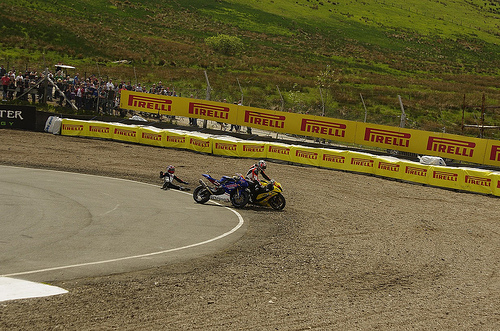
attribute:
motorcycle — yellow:
[232, 177, 287, 213]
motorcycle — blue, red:
[192, 172, 234, 203]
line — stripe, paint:
[1, 162, 243, 279]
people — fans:
[2, 66, 176, 120]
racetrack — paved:
[0, 160, 249, 286]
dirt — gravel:
[0, 129, 499, 327]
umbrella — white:
[53, 63, 75, 70]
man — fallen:
[157, 164, 193, 193]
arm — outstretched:
[175, 173, 190, 184]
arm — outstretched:
[157, 169, 166, 179]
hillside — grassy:
[1, 2, 500, 71]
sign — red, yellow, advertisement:
[62, 117, 88, 139]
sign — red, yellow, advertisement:
[83, 119, 112, 139]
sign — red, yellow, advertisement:
[111, 123, 139, 144]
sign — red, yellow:
[136, 127, 165, 146]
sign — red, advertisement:
[164, 129, 188, 150]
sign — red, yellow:
[186, 131, 213, 156]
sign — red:
[211, 137, 236, 158]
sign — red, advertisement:
[263, 142, 292, 166]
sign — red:
[293, 144, 316, 164]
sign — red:
[320, 145, 346, 172]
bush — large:
[205, 28, 246, 55]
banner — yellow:
[119, 85, 499, 163]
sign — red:
[354, 117, 419, 152]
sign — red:
[119, 87, 180, 117]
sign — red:
[183, 96, 240, 123]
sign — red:
[423, 130, 487, 164]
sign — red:
[375, 154, 405, 181]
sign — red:
[403, 155, 428, 186]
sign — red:
[429, 161, 462, 190]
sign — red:
[464, 166, 494, 195]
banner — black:
[0, 102, 38, 130]